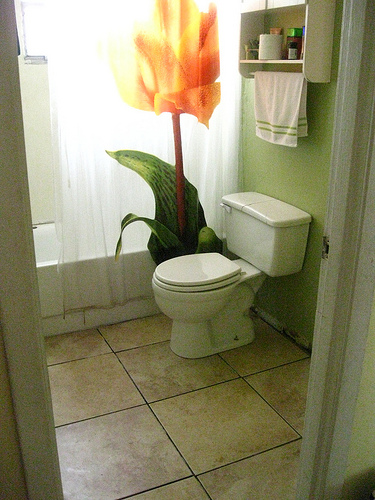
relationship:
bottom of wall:
[248, 303, 311, 352] [228, 0, 346, 354]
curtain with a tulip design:
[41, 1, 240, 317] [103, 1, 222, 268]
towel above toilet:
[251, 70, 314, 149] [142, 188, 314, 371]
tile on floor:
[147, 371, 304, 477] [35, 303, 309, 499]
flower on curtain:
[105, 1, 228, 260] [24, 0, 235, 311]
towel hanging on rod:
[251, 70, 314, 149] [244, 66, 302, 80]